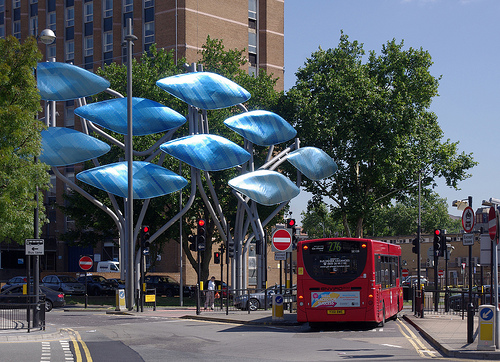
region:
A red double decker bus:
[296, 234, 405, 330]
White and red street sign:
[271, 223, 292, 255]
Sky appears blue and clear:
[284, 1, 498, 224]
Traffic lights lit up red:
[134, 217, 451, 264]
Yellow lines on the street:
[61, 323, 95, 360]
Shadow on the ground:
[219, 308, 319, 334]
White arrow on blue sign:
[475, 304, 496, 323]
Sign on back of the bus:
[306, 287, 364, 307]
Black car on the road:
[2, 281, 65, 314]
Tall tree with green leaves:
[286, 28, 478, 242]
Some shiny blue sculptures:
[31, 63, 334, 201]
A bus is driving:
[295, 238, 405, 327]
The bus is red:
[297, 238, 405, 326]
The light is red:
[431, 228, 441, 235]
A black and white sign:
[25, 236, 44, 257]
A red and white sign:
[271, 228, 291, 250]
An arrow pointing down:
[480, 306, 495, 323]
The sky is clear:
[437, 18, 485, 97]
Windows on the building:
[9, 1, 151, 64]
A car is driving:
[2, 281, 60, 309]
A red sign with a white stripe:
[262, 223, 299, 253]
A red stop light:
[430, 222, 446, 257]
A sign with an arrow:
[17, 233, 59, 264]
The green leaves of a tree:
[341, 79, 424, 161]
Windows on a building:
[62, 1, 122, 62]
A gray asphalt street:
[121, 317, 236, 360]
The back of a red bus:
[285, 236, 400, 332]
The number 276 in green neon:
[317, 236, 354, 256]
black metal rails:
[435, 285, 467, 322]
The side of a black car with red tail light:
[0, 275, 70, 314]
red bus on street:
[225, 207, 465, 359]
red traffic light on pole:
[177, 202, 215, 330]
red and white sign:
[260, 220, 301, 252]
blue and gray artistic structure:
[37, 58, 314, 301]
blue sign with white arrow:
[465, 299, 498, 323]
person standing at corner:
[164, 245, 290, 349]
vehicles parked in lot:
[39, 255, 239, 327]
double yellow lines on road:
[29, 300, 218, 357]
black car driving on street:
[4, 276, 184, 333]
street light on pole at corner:
[0, 18, 93, 353]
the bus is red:
[284, 203, 414, 351]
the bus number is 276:
[317, 230, 359, 258]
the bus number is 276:
[308, 225, 368, 274]